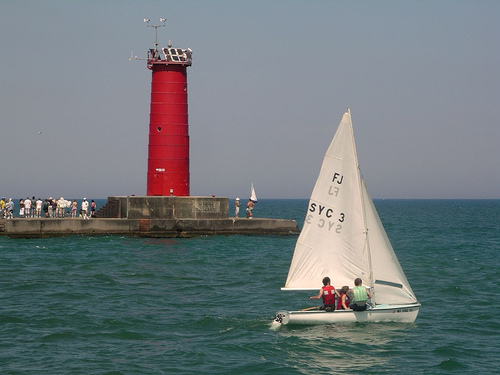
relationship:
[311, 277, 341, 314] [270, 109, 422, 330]
man on sailboat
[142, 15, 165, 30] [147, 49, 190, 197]
light on light house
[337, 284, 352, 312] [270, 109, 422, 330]
woman on sailboat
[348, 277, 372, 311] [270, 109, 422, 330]
man on sailboat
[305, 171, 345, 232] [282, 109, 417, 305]
writing on sails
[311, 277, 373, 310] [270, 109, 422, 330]
people are on sailboat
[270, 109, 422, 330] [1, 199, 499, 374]
sailboat on water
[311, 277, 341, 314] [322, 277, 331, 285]
man has hair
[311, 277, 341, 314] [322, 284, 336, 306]
man wearing a life jacket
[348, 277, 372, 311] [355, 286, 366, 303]
man wearing a life jacket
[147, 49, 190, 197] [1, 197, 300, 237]
light house on pier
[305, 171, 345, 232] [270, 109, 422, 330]
writing on sailboat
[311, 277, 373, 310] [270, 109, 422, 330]
people on sailboat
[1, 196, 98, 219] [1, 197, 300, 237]
people on pier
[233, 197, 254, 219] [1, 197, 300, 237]
people on pier